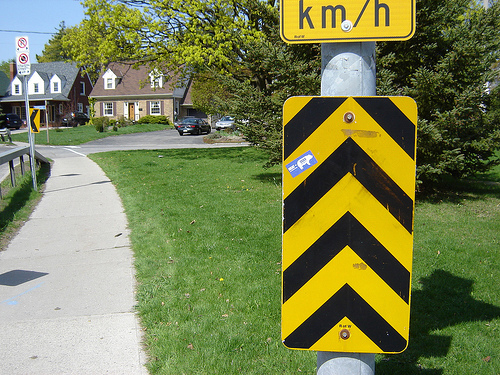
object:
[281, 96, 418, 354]
sign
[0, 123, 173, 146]
lawn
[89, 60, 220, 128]
house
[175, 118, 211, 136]
car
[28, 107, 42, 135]
sign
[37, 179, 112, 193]
shadow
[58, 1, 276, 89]
flowers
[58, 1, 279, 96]
tree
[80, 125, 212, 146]
driveway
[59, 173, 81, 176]
shadow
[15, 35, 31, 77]
sign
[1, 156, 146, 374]
sidewalk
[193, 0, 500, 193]
evergreen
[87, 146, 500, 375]
grass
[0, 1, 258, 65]
sky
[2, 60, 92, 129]
house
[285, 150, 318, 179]
sticker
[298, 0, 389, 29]
text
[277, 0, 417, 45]
sign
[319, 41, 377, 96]
pole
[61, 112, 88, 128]
car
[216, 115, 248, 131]
car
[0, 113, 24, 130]
car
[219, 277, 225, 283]
dandelion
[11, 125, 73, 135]
driveway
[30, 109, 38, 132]
arrow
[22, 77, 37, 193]
sign post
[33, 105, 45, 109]
street sign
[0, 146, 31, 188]
guard rail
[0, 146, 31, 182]
road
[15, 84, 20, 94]
window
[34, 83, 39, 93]
window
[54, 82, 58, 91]
window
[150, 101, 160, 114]
shutters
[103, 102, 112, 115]
shutters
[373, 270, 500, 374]
shadow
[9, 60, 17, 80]
chimney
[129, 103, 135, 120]
front door